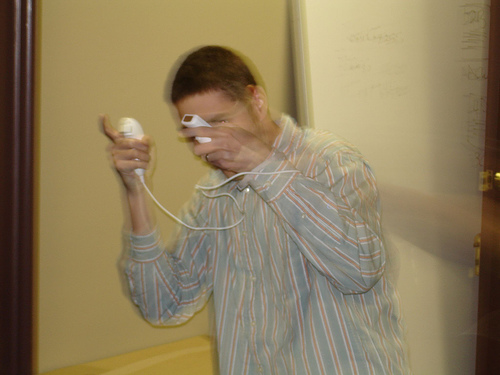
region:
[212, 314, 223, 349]
Red stripe on mans shirt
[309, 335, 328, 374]
Red stripe on mans shirt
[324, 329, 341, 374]
Red stripe on mans shirt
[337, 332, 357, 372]
Red stripe on mans shirt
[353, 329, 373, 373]
Red stripe on mans shirt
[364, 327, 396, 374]
Red stripe on mans shirt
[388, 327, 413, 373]
Red stripe on mans shirt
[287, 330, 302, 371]
Red stripe on mans shirt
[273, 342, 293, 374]
Red stripe on mans shirt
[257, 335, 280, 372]
Red stripe on mans shirt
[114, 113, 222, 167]
Game controllers in man's hands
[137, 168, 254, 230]
White cord on game controller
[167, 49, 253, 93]
Short dark hair on man's head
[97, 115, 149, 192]
Hand gripping game controller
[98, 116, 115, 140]
Index finger pointed upward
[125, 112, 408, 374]
Striped shirt on a man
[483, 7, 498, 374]
Edge of wooden door near man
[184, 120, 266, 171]
Hand holding a game controller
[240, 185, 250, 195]
Button on man's shirt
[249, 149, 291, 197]
Sewn cuff of a shirt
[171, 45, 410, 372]
A man hiding from the camera.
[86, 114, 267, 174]
Two game controllers in the man's hands.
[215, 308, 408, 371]
The man's blue shirt with red and white stripes.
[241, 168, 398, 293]
The long sleeve of the man's shirt.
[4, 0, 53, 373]
The dark drapes in the room.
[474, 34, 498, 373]
The dark wooden door.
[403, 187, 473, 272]
The shadow on the wall.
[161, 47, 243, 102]
The man's short brown hair.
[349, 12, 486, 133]
Dark colored writing on the wall.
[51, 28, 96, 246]
The mustard colored wall.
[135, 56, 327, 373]
man playing video games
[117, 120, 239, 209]
wii remote in hands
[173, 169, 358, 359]
blue striped shirt on man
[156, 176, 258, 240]
white wire on controller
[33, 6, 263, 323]
tan wall by man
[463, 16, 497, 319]
brown door on right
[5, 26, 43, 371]
brown door frame on left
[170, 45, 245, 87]
black hair of man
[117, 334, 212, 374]
yellow couch near man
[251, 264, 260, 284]
small buttons on shirt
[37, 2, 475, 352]
the image is blurry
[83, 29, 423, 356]
the man is playing a game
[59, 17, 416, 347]
the man is in motion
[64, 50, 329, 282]
the man is holding a remote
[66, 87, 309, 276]
the remotes are white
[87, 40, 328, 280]
the man has a remote in both hands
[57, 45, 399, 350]
the man`s shirt is striped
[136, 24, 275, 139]
the man has brown hair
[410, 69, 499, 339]
the door is slightly open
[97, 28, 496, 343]
the door is behind the man